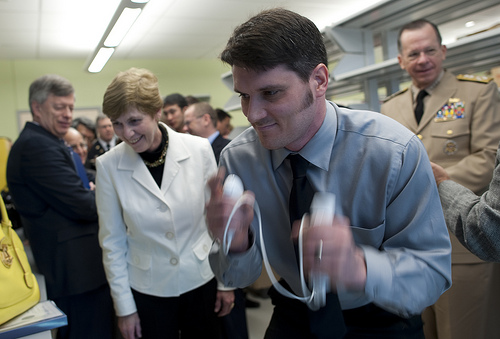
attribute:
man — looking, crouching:
[206, 7, 459, 334]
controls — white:
[211, 172, 350, 308]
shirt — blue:
[208, 99, 455, 318]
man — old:
[371, 17, 499, 337]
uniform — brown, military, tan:
[372, 68, 500, 333]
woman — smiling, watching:
[93, 65, 236, 328]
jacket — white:
[90, 132, 232, 311]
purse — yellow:
[4, 188, 40, 320]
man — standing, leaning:
[3, 72, 121, 336]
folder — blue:
[68, 145, 96, 192]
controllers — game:
[223, 172, 345, 309]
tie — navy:
[285, 153, 315, 284]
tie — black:
[411, 87, 433, 123]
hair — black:
[221, 7, 337, 106]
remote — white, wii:
[218, 172, 348, 310]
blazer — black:
[6, 123, 141, 299]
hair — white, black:
[30, 74, 77, 112]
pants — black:
[56, 282, 124, 338]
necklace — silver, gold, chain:
[141, 134, 173, 173]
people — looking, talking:
[3, 3, 496, 333]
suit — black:
[2, 123, 137, 336]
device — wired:
[216, 173, 344, 308]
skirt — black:
[128, 279, 216, 336]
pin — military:
[454, 110, 471, 123]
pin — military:
[456, 71, 494, 84]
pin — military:
[445, 95, 464, 104]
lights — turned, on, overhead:
[88, 0, 145, 77]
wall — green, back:
[5, 56, 268, 140]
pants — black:
[128, 276, 219, 332]